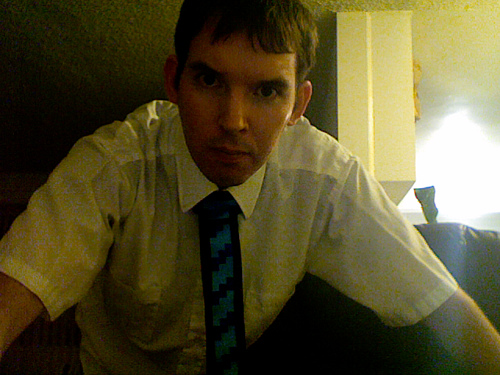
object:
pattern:
[208, 223, 240, 374]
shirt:
[0, 99, 461, 375]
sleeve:
[309, 158, 459, 333]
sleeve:
[4, 131, 121, 324]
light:
[395, 111, 500, 224]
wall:
[0, 0, 500, 235]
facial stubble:
[196, 156, 260, 188]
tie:
[192, 189, 247, 375]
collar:
[174, 121, 269, 222]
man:
[0, 0, 500, 375]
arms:
[306, 155, 499, 374]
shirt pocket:
[107, 274, 164, 347]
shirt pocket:
[243, 270, 322, 352]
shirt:
[73, 156, 199, 351]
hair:
[170, 0, 322, 121]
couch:
[239, 220, 499, 375]